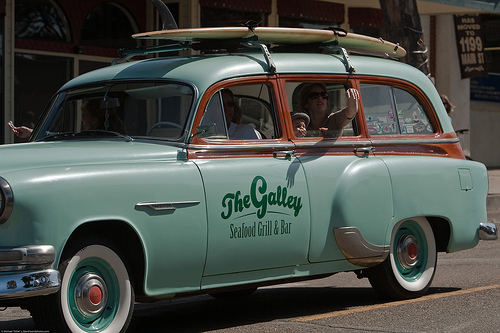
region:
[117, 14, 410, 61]
surfboard on top of car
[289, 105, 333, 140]
baby looking out the window of the car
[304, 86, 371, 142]
person with arm stuck out of back window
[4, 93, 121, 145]
person handing something out of the window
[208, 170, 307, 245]
restaurant name on side of door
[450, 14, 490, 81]
black and white sign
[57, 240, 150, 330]
white walled tire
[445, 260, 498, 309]
yellow line painted on road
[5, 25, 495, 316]
old style car driving down the road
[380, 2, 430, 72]
tree in the sidewalk behind the car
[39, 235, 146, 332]
Front wheel of green car.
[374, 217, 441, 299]
Back wheel of green car.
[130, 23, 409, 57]
White surfboard on top of car.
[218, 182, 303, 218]
'The Galley' written in green.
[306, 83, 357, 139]
A woman riding in the backseat.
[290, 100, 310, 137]
A child riding in the back seat.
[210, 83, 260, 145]
A woman in white in the driver's seat.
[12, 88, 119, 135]
A person riding in the front passenger's seat.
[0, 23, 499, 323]
Mint green car with a surfboard on top of it,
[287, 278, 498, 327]
Yellow line painted on street.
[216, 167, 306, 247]
The Galley Seafood Grill & Bar logo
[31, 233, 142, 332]
white wall tire on vintage car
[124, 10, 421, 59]
surfboard on top of vintage car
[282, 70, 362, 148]
woman and child looking out car window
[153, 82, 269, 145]
driver of car wearing sun glasses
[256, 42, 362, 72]
surfboard racks on top of car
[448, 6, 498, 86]
sign notifying of new store location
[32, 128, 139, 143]
windshield wipers on antique car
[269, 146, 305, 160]
door handle on driver's door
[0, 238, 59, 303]
silver chrome fender on car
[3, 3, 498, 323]
an antique woody car on the street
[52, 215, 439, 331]
the cat has white wall tires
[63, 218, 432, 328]
the wheels are light green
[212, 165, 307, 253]
advertisement is on the door of the car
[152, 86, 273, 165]
a person is driving the car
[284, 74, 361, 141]
a lady is waving her hand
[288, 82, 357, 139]
a baby is in the lady's lap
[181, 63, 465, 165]
wood trim is around the windows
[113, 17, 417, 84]
a surfboard is on the roof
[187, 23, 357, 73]
a rack with straps is on the car